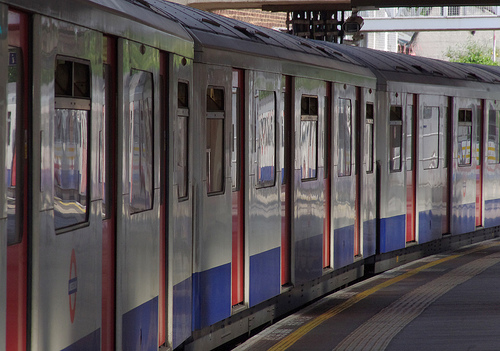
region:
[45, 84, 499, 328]
red white and blue train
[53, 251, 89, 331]
red and blue logo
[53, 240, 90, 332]
logo on train doors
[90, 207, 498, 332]
blue stripes on train doors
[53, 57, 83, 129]
train windows are lowered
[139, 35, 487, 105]
dark roof on train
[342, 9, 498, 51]
metal beam over train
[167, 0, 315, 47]
brick building behind train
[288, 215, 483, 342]
yellow stripe on platform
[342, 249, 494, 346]
white bricks on platform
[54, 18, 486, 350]
a train around a curve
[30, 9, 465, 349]
a silver train around a curve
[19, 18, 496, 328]
an old train around a curve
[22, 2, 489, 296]
a silver train with blue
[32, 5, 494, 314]
a train on a track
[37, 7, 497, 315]
an old train on a track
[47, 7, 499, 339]
a train next to a sidewalk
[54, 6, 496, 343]
an old train next to sidewalk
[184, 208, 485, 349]
a sidewalk with yellow line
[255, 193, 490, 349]
a yellow line going down a sidewalk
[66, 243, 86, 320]
logo on door of subway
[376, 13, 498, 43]
steel beam above subway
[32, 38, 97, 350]
first subway door on subway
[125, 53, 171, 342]
second subway door on subway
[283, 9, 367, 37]
metal equipment to run subway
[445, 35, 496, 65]
green tree behind subway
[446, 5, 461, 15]
window in a nearby building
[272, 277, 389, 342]
Yellow boundary line near subway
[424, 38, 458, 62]
siding on nearby house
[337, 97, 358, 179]
Window in subway door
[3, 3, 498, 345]
red and blue passenger train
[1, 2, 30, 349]
red door on passenger train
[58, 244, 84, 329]
company logo on train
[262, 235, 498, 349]
yellow safety boundary line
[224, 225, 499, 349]
curved black train platform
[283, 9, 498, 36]
white metal support beam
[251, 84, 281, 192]
reflection in train window glass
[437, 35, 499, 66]
green leafy tree in background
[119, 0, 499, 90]
black passenger train roof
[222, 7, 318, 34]
brick building wall in background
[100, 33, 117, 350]
Red door on train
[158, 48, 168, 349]
Red door on train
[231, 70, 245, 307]
Red door on train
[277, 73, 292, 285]
Red door on train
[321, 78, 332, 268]
Red door on train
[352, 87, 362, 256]
Red door on train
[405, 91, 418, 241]
Red door on train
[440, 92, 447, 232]
Red door on train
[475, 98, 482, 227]
Red door on train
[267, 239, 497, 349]
Yellow curved line next to train